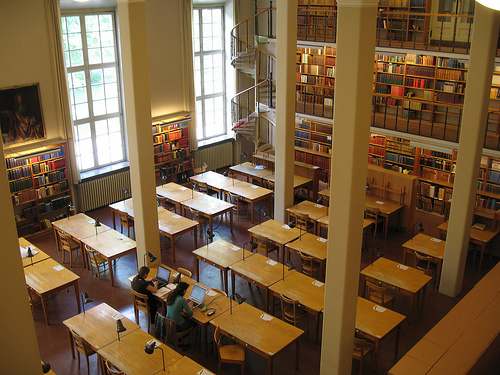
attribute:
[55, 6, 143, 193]
windows — Long 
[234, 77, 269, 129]
staircase — winding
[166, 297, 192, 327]
shirt — green, long sleeve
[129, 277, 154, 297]
shirt — short sleeve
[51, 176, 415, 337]
tables — brown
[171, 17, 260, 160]
window — tall